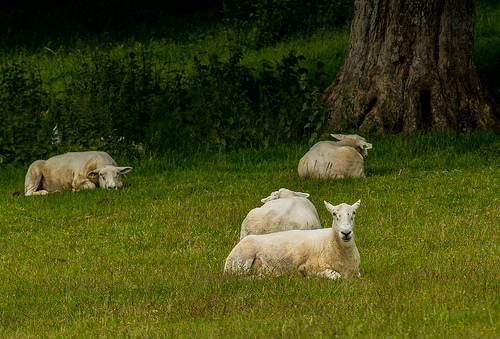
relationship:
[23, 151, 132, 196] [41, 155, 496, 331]
animal in field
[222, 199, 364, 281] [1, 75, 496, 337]
animal in field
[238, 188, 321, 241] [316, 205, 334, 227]
animal in grass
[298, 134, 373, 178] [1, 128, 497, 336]
animal on grass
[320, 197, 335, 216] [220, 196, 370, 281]
ear of cow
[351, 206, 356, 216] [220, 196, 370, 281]
eye of cow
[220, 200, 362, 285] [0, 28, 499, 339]
animal in field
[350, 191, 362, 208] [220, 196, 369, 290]
ear of animal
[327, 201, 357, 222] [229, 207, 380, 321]
eyes of animal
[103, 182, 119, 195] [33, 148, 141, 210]
mouth of animal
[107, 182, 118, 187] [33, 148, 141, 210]
nose of animal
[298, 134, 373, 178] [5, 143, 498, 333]
animal in field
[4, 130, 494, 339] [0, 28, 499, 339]
patch of field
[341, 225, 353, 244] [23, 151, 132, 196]
mouth of animal